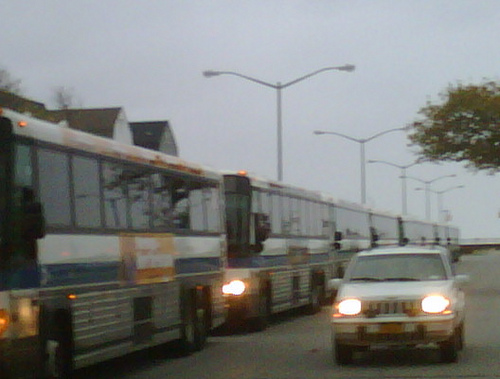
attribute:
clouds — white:
[365, 35, 400, 55]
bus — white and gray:
[11, 102, 481, 333]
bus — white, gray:
[0, 126, 216, 343]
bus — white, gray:
[0, 162, 262, 344]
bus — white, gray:
[327, 192, 407, 307]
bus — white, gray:
[322, 190, 399, 296]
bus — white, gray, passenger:
[373, 213, 404, 243]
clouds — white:
[125, 21, 372, 136]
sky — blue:
[55, 22, 493, 200]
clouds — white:
[164, 29, 342, 126]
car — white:
[327, 243, 470, 369]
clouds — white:
[60, 7, 169, 74]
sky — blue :
[2, 1, 493, 238]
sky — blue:
[77, 19, 177, 84]